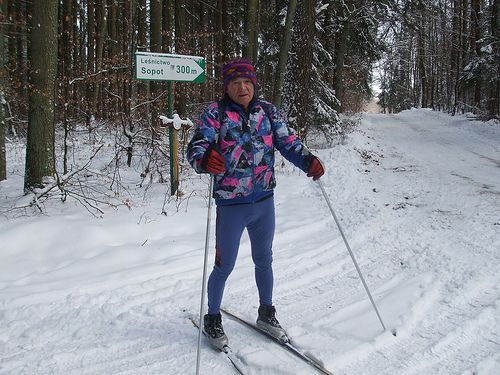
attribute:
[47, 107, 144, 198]
patch — pink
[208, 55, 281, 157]
skier — colorful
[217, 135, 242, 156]
patch — pink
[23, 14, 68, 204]
trunk — brown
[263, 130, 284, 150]
patch — pink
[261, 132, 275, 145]
patch — pink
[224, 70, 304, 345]
skiier — older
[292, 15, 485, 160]
woods — snowy